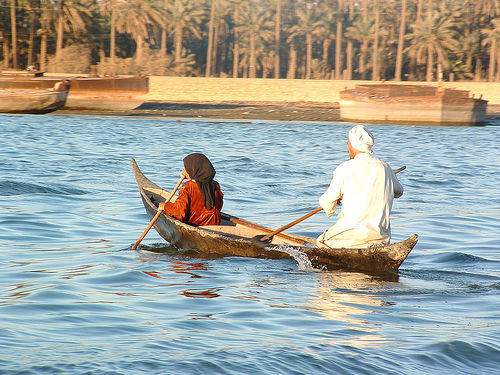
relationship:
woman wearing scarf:
[157, 153, 224, 226] [183, 153, 217, 209]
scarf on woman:
[183, 153, 217, 209] [157, 153, 224, 226]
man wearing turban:
[316, 124, 403, 248] [347, 124, 375, 154]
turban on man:
[347, 124, 375, 154] [316, 124, 403, 248]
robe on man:
[317, 152, 403, 247] [316, 124, 403, 248]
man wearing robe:
[316, 124, 403, 248] [317, 152, 403, 247]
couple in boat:
[157, 124, 404, 249] [131, 158, 417, 266]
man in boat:
[316, 124, 403, 248] [131, 158, 417, 266]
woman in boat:
[157, 153, 224, 226] [131, 158, 417, 266]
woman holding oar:
[157, 153, 224, 226] [131, 173, 186, 249]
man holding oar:
[316, 124, 403, 248] [260, 165, 405, 240]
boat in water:
[131, 158, 417, 266] [0, 113, 499, 374]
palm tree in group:
[273, 4, 281, 79] [1, 0, 498, 82]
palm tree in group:
[401, 9, 462, 81] [1, 0, 498, 82]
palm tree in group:
[344, 17, 388, 82] [1, 0, 498, 82]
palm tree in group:
[205, 0, 215, 78] [1, 0, 498, 82]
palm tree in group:
[394, 0, 406, 82] [1, 0, 498, 82]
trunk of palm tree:
[394, 60, 402, 80] [394, 0, 406, 82]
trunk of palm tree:
[425, 67, 434, 82] [401, 9, 462, 81]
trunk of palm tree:
[358, 64, 365, 79] [344, 17, 388, 82]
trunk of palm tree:
[274, 65, 279, 78] [273, 4, 281, 79]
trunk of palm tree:
[204, 64, 211, 77] [205, 0, 215, 78]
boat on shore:
[0, 78, 72, 113] [0, 70, 498, 123]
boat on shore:
[58, 75, 147, 111] [0, 70, 498, 123]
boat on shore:
[338, 83, 487, 125] [0, 70, 498, 123]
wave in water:
[416, 251, 498, 266] [0, 113, 499, 374]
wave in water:
[0, 177, 103, 197] [0, 113, 499, 374]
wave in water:
[210, 155, 263, 165] [0, 113, 499, 374]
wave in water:
[0, 340, 497, 372] [0, 113, 499, 374]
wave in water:
[399, 177, 465, 185] [0, 113, 499, 374]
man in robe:
[316, 124, 403, 248] [317, 152, 403, 247]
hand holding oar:
[180, 168, 189, 178] [131, 173, 186, 249]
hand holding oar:
[157, 202, 165, 210] [131, 173, 186, 249]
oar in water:
[131, 173, 186, 249] [0, 113, 499, 374]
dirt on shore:
[109, 100, 499, 123] [0, 70, 498, 123]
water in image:
[0, 113, 499, 374] [1, 0, 499, 373]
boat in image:
[131, 158, 417, 266] [1, 0, 499, 373]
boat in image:
[0, 78, 72, 113] [1, 0, 499, 373]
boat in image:
[58, 75, 147, 111] [1, 0, 499, 373]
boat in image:
[338, 83, 487, 125] [1, 0, 499, 373]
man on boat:
[316, 124, 403, 248] [131, 158, 417, 266]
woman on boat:
[157, 153, 224, 226] [131, 158, 417, 266]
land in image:
[0, 70, 498, 123] [1, 0, 499, 373]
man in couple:
[316, 124, 403, 248] [157, 124, 404, 249]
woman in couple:
[157, 153, 224, 226] [157, 124, 404, 249]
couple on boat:
[157, 124, 404, 249] [131, 158, 417, 266]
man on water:
[316, 124, 403, 248] [0, 113, 499, 374]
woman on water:
[157, 153, 224, 226] [0, 113, 499, 374]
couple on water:
[157, 124, 404, 249] [0, 113, 499, 374]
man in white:
[316, 124, 403, 248] [307, 124, 403, 248]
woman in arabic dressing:
[157, 153, 224, 226] [164, 153, 223, 224]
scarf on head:
[183, 153, 217, 209] [183, 153, 215, 182]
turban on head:
[347, 124, 375, 154] [346, 126, 374, 159]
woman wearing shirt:
[157, 153, 224, 226] [164, 179, 224, 225]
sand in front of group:
[0, 72, 499, 105] [1, 0, 498, 82]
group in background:
[1, 0, 498, 82] [1, 1, 499, 126]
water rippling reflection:
[0, 113, 499, 374] [137, 255, 416, 348]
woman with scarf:
[157, 153, 224, 226] [183, 153, 217, 209]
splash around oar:
[264, 243, 327, 272] [260, 165, 405, 240]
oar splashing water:
[260, 165, 405, 240] [0, 113, 499, 374]